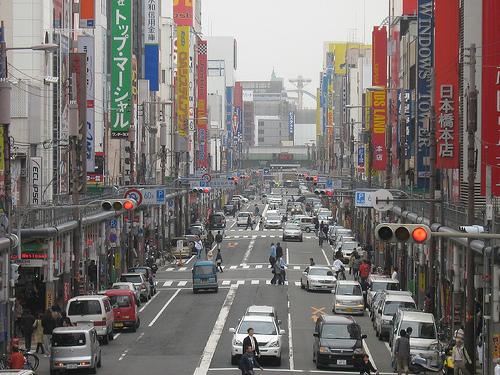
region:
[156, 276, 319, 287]
Crosswalk on a busy street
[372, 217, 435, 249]
Traffic signal for busy street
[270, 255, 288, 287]
Pedestrians crossing the street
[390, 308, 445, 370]
SUV parked on the street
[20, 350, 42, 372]
Wheels of a bicycle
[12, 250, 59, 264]
Electric sign for business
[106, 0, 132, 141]
Banner hung on building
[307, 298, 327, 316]
Red X painted on the street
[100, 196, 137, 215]
Stop light for traffic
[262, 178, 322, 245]
Crowded city street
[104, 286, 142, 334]
Red van parked in front of white van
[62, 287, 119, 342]
White van parked in front of gray car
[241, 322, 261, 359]
Person crossing street in front of white car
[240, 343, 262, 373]
Person crossing street in front of white car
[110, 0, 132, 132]
Green Chinese sign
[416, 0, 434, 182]
Blue English sign behind red Chinese sign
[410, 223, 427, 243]
Light on traffic light is red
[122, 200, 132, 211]
Light on traffic light is red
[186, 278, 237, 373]
White traffic line on street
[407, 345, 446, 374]
Blue scooter in front of white van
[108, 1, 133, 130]
Green and white sign with Asian characters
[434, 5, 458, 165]
Red and silver sign with Asian characters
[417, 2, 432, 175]
Blue sign reading Windows Tower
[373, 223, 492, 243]
Red traffic light on silver pole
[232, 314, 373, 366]
Row of cars stopped at traffic light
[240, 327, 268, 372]
People walking in front of white car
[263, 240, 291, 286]
People crossing street at crosswalk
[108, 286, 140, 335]
Red vehicle parked on side of road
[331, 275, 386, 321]
White vehicle double parked on side of road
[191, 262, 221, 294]
Blue van driving down road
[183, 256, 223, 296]
car on the street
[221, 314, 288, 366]
car on the street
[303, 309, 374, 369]
car on the street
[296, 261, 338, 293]
car on the street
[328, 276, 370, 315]
car on the street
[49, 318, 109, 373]
car on the street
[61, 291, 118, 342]
car on the street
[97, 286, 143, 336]
car on the street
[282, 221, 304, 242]
car on the street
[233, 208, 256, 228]
car on the street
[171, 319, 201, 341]
Small part of a black street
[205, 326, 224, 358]
A solid white line on the street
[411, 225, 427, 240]
Red streetlight on the right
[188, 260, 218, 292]
Teal and gray mini-van on the street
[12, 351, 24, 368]
Red shirt of pedestrian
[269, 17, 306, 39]
A white overcast sky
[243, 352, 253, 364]
Dark blue shirt of civilian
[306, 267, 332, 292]
White car on the street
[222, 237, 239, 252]
Yellow sign on the street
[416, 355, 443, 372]
Gray moped on the side of the street